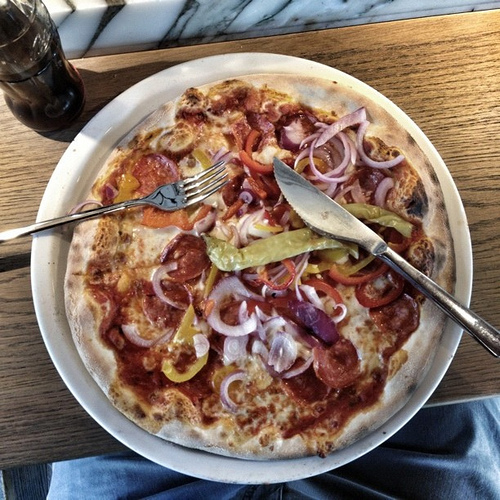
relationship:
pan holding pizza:
[28, 51, 474, 487] [62, 72, 457, 463]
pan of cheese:
[28, 51, 474, 487] [62, 74, 455, 461]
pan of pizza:
[28, 51, 474, 487] [62, 72, 457, 463]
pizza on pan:
[62, 72, 457, 463] [28, 51, 474, 487]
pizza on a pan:
[62, 72, 457, 463] [28, 51, 474, 487]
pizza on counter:
[62, 72, 457, 463] [0, 9, 500, 469]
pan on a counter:
[28, 51, 474, 487] [0, 9, 500, 469]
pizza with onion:
[62, 72, 457, 463] [291, 102, 404, 207]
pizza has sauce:
[62, 72, 457, 463] [107, 324, 385, 440]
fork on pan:
[0, 161, 229, 245] [28, 51, 474, 487]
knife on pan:
[271, 152, 499, 355] [28, 51, 474, 487]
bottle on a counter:
[0, 1, 87, 135] [0, 9, 500, 469]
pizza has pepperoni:
[62, 72, 457, 463] [162, 235, 209, 280]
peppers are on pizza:
[238, 129, 292, 196] [62, 72, 457, 463]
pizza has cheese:
[62, 72, 457, 463] [100, 91, 392, 433]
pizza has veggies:
[62, 72, 457, 463] [158, 106, 415, 414]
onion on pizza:
[291, 102, 404, 207] [62, 72, 457, 463]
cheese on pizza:
[100, 91, 392, 433] [62, 72, 457, 463]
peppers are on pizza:
[161, 296, 210, 384] [62, 72, 457, 463]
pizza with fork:
[62, 72, 457, 463] [0, 161, 229, 245]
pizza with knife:
[62, 72, 457, 463] [271, 152, 499, 355]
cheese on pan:
[62, 74, 455, 461] [28, 51, 474, 487]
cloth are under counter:
[48, 397, 498, 499] [0, 9, 500, 469]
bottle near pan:
[0, 1, 87, 135] [28, 51, 474, 487]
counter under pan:
[0, 9, 500, 469] [28, 51, 474, 487]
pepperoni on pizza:
[162, 235, 209, 280] [62, 72, 457, 463]